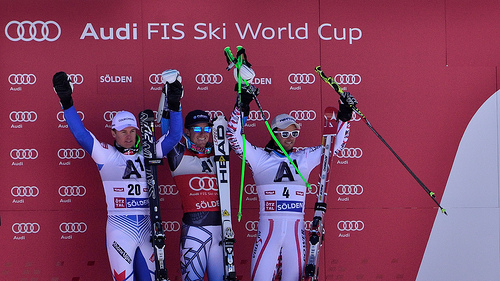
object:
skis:
[135, 109, 165, 269]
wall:
[0, 0, 499, 281]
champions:
[53, 45, 361, 278]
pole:
[313, 65, 449, 216]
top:
[168, 145, 223, 225]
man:
[52, 68, 184, 280]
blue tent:
[381, 79, 494, 126]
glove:
[338, 92, 358, 122]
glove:
[234, 82, 260, 117]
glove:
[161, 79, 184, 111]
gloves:
[52, 71, 75, 111]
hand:
[51, 71, 81, 98]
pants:
[107, 213, 159, 280]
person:
[226, 82, 358, 281]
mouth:
[125, 139, 133, 143]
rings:
[4, 19, 366, 233]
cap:
[111, 110, 140, 131]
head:
[110, 111, 137, 148]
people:
[51, 63, 360, 281]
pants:
[249, 212, 310, 281]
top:
[227, 110, 352, 216]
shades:
[193, 126, 211, 133]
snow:
[415, 90, 499, 281]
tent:
[472, 73, 499, 102]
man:
[161, 68, 259, 281]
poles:
[223, 44, 314, 222]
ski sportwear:
[109, 213, 163, 255]